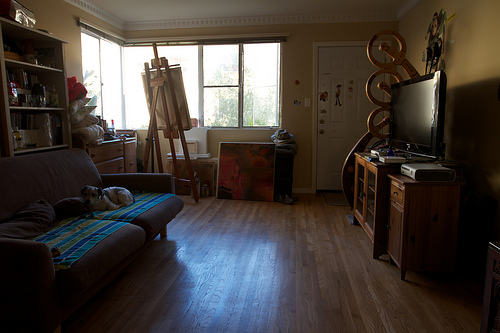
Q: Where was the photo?
A: In a living room.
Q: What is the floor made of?
A: Wood.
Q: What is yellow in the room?
A: The walls.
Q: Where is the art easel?
A: In the room.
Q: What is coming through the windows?
A: Sunlight.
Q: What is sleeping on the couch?
A: Dogs.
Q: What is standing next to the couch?
A: An easel.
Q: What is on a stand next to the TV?
A: An Xbox.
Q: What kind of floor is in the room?
A: Hardwood.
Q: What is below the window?
A: A painting.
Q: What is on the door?
A: Stickers.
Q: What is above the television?
A: A plate.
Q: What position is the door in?
A: Closed.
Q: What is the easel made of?
A: Wood.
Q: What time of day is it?
A: Noon.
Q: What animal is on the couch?
A: Dog.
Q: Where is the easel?
A: In front of window.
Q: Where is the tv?
A: Entertainment center.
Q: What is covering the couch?
A: Towel.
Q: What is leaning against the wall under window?
A: Painting.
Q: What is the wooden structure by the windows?
A: Easel.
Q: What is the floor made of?
A: Wood.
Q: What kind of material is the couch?
A: Fabric.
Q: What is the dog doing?
A: Laying on couch.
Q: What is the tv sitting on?
A: A stand.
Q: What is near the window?
A: An easel.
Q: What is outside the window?
A: Trees.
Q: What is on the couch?
A: Sheet.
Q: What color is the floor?
A: Brown.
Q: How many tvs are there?
A: One.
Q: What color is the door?
A: White.